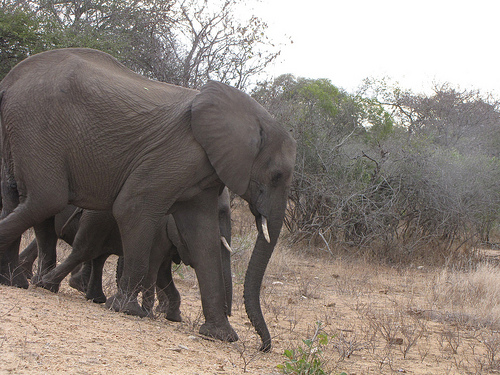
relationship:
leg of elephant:
[100, 181, 200, 326] [0, 47, 295, 352]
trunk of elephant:
[240, 231, 279, 301] [0, 47, 295, 352]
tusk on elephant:
[205, 199, 294, 271] [0, 47, 295, 352]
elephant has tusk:
[0, 47, 295, 352] [205, 199, 294, 271]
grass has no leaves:
[306, 245, 409, 341] [312, 177, 444, 288]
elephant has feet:
[0, 47, 295, 352] [152, 231, 258, 375]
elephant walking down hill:
[4, 34, 309, 372] [67, 96, 322, 344]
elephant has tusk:
[4, 34, 309, 372] [205, 199, 294, 271]